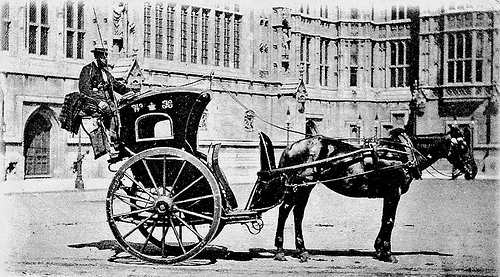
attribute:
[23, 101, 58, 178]
door — large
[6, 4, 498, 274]
picture — black, white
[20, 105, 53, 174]
door — large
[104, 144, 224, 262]
wheel — large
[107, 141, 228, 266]
wheel — brown, large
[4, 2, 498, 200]
building — very old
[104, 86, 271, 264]
carriage — small